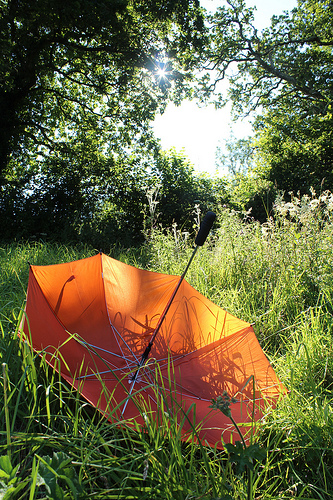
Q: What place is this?
A: It is a field.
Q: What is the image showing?
A: It is showing a field.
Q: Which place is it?
A: It is a field.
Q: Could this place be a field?
A: Yes, it is a field.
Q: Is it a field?
A: Yes, it is a field.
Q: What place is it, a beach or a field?
A: It is a field.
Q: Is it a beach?
A: No, it is a field.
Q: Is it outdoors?
A: Yes, it is outdoors.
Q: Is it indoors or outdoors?
A: It is outdoors.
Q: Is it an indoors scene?
A: No, it is outdoors.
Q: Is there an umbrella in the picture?
A: Yes, there is an umbrella.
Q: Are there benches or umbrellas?
A: Yes, there is an umbrella.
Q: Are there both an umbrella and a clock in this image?
A: No, there is an umbrella but no clocks.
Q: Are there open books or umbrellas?
A: Yes, there is an open umbrella.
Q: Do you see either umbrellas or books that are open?
A: Yes, the umbrella is open.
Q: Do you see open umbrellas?
A: Yes, there is an open umbrella.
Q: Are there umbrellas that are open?
A: Yes, there is an umbrella that is open.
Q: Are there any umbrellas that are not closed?
A: Yes, there is a open umbrella.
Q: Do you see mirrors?
A: No, there are no mirrors.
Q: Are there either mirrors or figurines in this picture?
A: No, there are no mirrors or figurines.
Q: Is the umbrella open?
A: Yes, the umbrella is open.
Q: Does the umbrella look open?
A: Yes, the umbrella is open.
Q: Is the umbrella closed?
A: No, the umbrella is open.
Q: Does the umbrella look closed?
A: No, the umbrella is open.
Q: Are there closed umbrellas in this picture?
A: No, there is an umbrella but it is open.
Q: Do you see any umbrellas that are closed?
A: No, there is an umbrella but it is open.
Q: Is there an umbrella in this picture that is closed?
A: No, there is an umbrella but it is open.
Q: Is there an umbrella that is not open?
A: No, there is an umbrella but it is open.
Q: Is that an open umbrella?
A: Yes, that is an open umbrella.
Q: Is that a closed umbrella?
A: No, that is an open umbrella.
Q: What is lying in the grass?
A: The umbrella is lying in the grass.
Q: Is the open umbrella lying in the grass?
A: Yes, the umbrella is lying in the grass.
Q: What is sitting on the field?
A: The umbrella is sitting on the field.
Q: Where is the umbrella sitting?
A: The umbrella is sitting on the field.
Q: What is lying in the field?
A: The umbrella is lying in the field.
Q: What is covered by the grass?
A: The umbrella is covered by the grass.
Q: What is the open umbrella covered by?
A: The umbrella is covered by the grass.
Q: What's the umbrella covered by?
A: The umbrella is covered by the grass.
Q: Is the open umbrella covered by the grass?
A: Yes, the umbrella is covered by the grass.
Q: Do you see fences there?
A: No, there are no fences.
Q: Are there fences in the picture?
A: No, there are no fences.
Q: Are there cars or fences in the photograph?
A: No, there are no fences or cars.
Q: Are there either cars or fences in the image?
A: No, there are no fences or cars.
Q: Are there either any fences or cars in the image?
A: No, there are no fences or cars.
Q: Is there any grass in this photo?
A: Yes, there is grass.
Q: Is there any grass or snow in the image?
A: Yes, there is grass.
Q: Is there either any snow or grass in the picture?
A: Yes, there is grass.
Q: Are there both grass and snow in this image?
A: No, there is grass but no snow.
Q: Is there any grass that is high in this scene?
A: Yes, there is high grass.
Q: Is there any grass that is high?
A: Yes, there is grass that is high.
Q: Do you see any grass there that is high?
A: Yes, there is grass that is high.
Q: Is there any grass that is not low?
A: Yes, there is high grass.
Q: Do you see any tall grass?
A: Yes, there is tall grass.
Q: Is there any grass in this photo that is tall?
A: Yes, there is grass that is tall.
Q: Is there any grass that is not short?
A: Yes, there is tall grass.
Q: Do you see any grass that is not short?
A: Yes, there is tall grass.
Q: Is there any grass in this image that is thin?
A: Yes, there is thin grass.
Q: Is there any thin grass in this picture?
A: Yes, there is thin grass.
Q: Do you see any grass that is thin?
A: Yes, there is grass that is thin.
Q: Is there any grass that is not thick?
A: Yes, there is thin grass.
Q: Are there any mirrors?
A: No, there are no mirrors.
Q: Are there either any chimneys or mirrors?
A: No, there are no mirrors or chimneys.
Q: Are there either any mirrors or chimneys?
A: No, there are no mirrors or chimneys.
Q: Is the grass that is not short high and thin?
A: Yes, the grass is high and thin.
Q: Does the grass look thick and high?
A: No, the grass is high but thin.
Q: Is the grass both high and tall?
A: Yes, the grass is high and tall.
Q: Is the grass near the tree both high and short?
A: No, the grass is high but tall.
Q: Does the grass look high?
A: Yes, the grass is high.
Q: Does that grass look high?
A: Yes, the grass is high.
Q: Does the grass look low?
A: No, the grass is high.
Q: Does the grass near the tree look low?
A: No, the grass is high.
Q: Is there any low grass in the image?
A: No, there is grass but it is high.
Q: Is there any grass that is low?
A: No, there is grass but it is high.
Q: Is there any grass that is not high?
A: No, there is grass but it is high.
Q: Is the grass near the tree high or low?
A: The grass is high.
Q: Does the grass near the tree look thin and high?
A: Yes, the grass is thin and high.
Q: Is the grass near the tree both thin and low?
A: No, the grass is thin but high.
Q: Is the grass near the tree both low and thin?
A: No, the grass is thin but high.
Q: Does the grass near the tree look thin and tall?
A: Yes, the grass is thin and tall.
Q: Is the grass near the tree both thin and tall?
A: Yes, the grass is thin and tall.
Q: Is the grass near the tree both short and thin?
A: No, the grass is thin but tall.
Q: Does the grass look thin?
A: Yes, the grass is thin.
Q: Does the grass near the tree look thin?
A: Yes, the grass is thin.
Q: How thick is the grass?
A: The grass is thin.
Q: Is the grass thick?
A: No, the grass is thin.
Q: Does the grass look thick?
A: No, the grass is thin.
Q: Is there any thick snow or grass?
A: No, there is grass but it is thin.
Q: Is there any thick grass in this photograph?
A: No, there is grass but it is thin.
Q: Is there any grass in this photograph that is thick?
A: No, there is grass but it is thin.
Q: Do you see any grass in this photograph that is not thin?
A: No, there is grass but it is thin.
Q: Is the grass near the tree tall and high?
A: Yes, the grass is tall and high.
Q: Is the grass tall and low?
A: No, the grass is tall but high.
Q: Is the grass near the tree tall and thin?
A: Yes, the grass is tall and thin.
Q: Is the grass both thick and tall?
A: No, the grass is tall but thin.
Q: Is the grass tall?
A: Yes, the grass is tall.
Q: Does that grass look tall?
A: Yes, the grass is tall.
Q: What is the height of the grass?
A: The grass is tall.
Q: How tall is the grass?
A: The grass is tall.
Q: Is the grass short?
A: No, the grass is tall.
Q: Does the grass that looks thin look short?
A: No, the grass is tall.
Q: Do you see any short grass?
A: No, there is grass but it is tall.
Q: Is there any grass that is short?
A: No, there is grass but it is tall.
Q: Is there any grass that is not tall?
A: No, there is grass but it is tall.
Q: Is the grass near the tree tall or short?
A: The grass is tall.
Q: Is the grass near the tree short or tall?
A: The grass is tall.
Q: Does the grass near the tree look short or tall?
A: The grass is tall.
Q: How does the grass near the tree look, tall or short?
A: The grass is tall.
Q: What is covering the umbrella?
A: The grass is covering the umbrella.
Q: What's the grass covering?
A: The grass is covering the umbrella.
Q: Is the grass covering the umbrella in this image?
A: Yes, the grass is covering the umbrella.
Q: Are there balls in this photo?
A: No, there are no balls.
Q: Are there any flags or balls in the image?
A: No, there are no balls or flags.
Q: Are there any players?
A: No, there are no players.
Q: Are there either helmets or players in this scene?
A: No, there are no players or helmets.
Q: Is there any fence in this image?
A: No, there are no fences.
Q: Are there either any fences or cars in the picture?
A: No, there are no fences or cars.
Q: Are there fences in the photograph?
A: No, there are no fences.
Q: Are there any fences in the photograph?
A: No, there are no fences.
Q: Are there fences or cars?
A: No, there are no fences or cars.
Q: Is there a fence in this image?
A: No, there are no fences.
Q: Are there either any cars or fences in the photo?
A: No, there are no fences or cars.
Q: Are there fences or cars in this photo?
A: No, there are no fences or cars.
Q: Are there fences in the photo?
A: No, there are no fences.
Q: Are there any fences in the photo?
A: No, there are no fences.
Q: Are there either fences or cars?
A: No, there are no fences or cars.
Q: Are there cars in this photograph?
A: No, there are no cars.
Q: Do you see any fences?
A: No, there are no fences.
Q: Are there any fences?
A: No, there are no fences.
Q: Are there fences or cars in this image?
A: No, there are no fences or cars.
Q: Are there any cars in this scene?
A: No, there are no cars.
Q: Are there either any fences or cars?
A: No, there are no cars or fences.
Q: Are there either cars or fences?
A: No, there are no cars or fences.